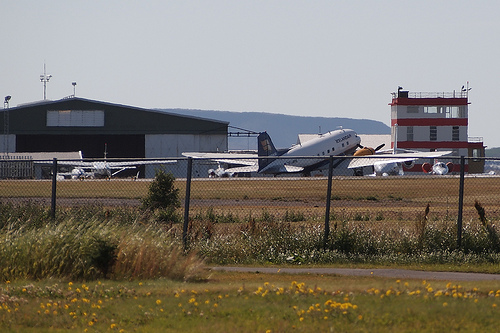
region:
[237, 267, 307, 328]
the grass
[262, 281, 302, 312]
the grass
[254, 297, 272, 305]
the grass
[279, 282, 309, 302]
the grass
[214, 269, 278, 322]
the grass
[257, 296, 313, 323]
the grass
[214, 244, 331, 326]
the grass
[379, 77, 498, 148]
red and white control tower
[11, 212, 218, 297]
cluster of tall weeds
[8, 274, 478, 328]
green grass and yellow flowers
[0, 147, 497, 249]
metal chain link fence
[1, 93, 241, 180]
gray and green airplane hanger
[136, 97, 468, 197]
large propeller driven airplane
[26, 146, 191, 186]
two small airplanes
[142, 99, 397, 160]
hill in the distance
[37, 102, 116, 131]
windows on the second floor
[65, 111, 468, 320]
a fence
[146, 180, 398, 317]
a fence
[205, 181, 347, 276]
a fence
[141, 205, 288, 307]
a fence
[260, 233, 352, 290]
a fence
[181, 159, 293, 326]
a fence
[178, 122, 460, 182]
a plane on the tarmac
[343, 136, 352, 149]
a window on the plane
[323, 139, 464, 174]
a wing on the plane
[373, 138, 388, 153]
a black propeller blade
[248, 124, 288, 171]
the tail of a plane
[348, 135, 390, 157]
the engine of a plane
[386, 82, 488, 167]
a red and white building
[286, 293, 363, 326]
yellow flowers on the ground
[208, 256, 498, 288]
a small asphalt road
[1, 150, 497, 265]
a chain link fence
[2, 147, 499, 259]
metal fence surrounding an airfield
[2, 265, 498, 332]
yellow flowers in the green grass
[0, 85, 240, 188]
hangar in an airport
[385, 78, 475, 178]
red and white air control tower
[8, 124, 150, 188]
open door to an airport hangar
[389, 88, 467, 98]
metal fence on the top of the control tower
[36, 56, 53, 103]
tall metal pole on the hangar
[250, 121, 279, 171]
blue tail of an airplane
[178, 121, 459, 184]
largest plane on the airplane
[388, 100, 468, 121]
top floor of the control tower